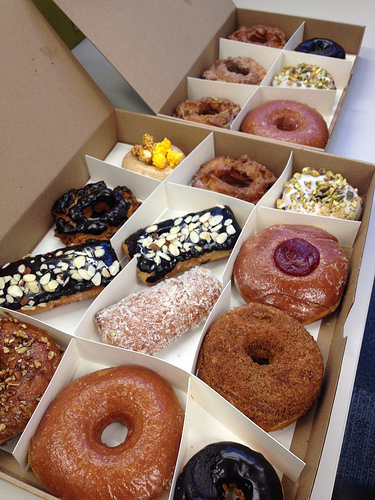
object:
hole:
[99, 420, 130, 451]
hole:
[218, 481, 245, 499]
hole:
[245, 338, 272, 367]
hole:
[273, 114, 293, 131]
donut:
[172, 440, 284, 499]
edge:
[94, 411, 130, 450]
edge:
[113, 106, 375, 194]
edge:
[322, 24, 366, 149]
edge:
[234, 6, 366, 35]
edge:
[293, 169, 374, 499]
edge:
[0, 465, 60, 499]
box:
[52, 0, 367, 157]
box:
[0, 0, 374, 499]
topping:
[93, 261, 222, 359]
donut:
[0, 312, 66, 449]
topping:
[44, 348, 55, 361]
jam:
[273, 235, 320, 277]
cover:
[0, 0, 114, 243]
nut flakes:
[224, 221, 237, 237]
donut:
[48, 179, 140, 247]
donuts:
[0, 237, 122, 319]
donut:
[275, 161, 363, 220]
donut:
[186, 148, 275, 205]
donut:
[232, 219, 350, 325]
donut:
[196, 301, 324, 433]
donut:
[121, 132, 184, 183]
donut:
[26, 364, 182, 499]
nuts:
[107, 256, 121, 278]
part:
[297, 248, 307, 262]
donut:
[227, 21, 286, 50]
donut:
[293, 35, 346, 60]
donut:
[199, 54, 269, 86]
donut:
[270, 60, 337, 92]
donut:
[170, 95, 241, 130]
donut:
[237, 99, 330, 151]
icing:
[171, 440, 282, 498]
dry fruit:
[274, 196, 286, 212]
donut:
[90, 263, 222, 356]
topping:
[162, 146, 182, 171]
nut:
[213, 227, 229, 249]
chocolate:
[124, 203, 242, 275]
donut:
[119, 203, 240, 287]